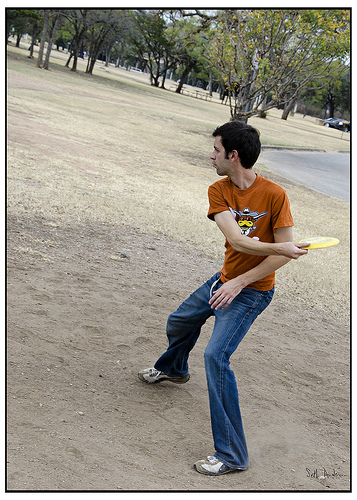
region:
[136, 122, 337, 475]
man in park playing with a Frisbee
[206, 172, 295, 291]
man wearing burnt orange Texas Longhorns t-shirt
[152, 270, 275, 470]
man wearing blue jeans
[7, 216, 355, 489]
ground is full of loose sand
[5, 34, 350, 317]
grass in area is mostly dormant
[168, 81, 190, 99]
picnic table on left under tree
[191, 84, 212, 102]
picnic table on tight under tree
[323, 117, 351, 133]
black car parked to right in parking lot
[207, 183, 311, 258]
man's right arm and hand across body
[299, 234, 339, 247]
Frisbee is bright yellow with black printing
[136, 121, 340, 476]
a man throwing a frisbee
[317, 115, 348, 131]
a parked car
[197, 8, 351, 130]
a tree with green and yellow leaves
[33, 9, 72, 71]
two trees side by side with white trunks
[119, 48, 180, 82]
a building in the distance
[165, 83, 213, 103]
three picnic benches in a row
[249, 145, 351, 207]
a corner of a parking lot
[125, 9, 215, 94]
two trees with dark, shadowed trunks and green leaves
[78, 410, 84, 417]
a small white rock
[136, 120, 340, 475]
a man looking to the left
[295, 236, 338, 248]
A yellow frisbee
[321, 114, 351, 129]
A couple of parked cars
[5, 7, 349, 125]
A large grouping of trees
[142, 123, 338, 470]
A young man throwing a frisbee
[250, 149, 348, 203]
Partial area of a parking lot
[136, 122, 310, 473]
A young man standing in a park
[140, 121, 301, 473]
A young man with short black hair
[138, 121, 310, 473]
A young man in the park wearing a orange tee shirt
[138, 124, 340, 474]
A young man in a tee shirt and blue jeans tossing a Frisbee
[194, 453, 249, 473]
A white and gray sneaker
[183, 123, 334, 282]
man holding a Frisbee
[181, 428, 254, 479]
shoe of the man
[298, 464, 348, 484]
name in bottom right corner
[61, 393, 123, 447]
dirt under the man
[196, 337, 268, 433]
pants on the man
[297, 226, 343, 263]
Frisbee in man's hand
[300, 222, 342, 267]
yellow and round Frisbee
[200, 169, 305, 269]
orange shirt on man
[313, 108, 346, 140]
car in the background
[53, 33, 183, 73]
trees in the distance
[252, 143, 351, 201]
a gray concrete area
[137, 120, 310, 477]
a man looking left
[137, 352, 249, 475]
a man with black and white shoes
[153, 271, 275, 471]
a man with blue jeans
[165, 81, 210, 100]
two picnic tables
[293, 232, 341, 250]
a man throwing yellow frisbee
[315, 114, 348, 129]
a small black car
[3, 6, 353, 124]
lots of green trees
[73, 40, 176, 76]
a house behind trees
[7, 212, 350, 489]
small area of gray sand